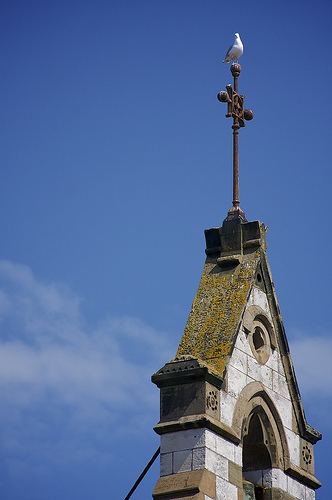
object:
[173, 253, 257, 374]
moss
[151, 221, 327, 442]
roof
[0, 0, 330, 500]
sky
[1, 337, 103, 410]
clouds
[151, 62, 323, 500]
building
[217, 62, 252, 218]
weather vane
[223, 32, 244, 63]
bird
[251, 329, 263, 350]
window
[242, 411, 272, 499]
window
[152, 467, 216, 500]
brown stone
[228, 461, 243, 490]
brown stone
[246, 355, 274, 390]
stones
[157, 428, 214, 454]
stones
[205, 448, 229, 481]
stones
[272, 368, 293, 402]
stones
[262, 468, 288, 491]
stones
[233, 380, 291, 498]
arch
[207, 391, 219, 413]
decorations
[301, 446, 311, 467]
decorations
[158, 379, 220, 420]
block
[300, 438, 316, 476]
block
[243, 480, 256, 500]
bell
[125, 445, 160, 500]
brace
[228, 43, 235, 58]
feathers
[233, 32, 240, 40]
head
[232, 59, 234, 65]
legs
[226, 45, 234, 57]
wing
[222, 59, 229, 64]
tail